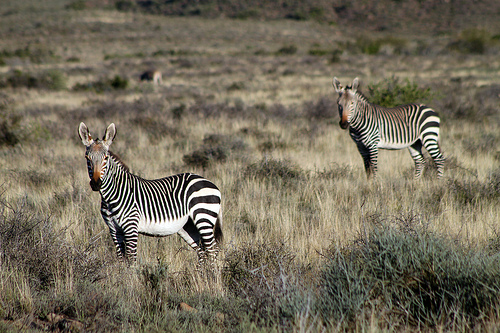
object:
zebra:
[79, 121, 225, 271]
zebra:
[332, 76, 447, 180]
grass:
[0, 0, 500, 333]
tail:
[214, 204, 224, 249]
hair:
[214, 216, 225, 243]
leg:
[422, 131, 445, 180]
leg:
[192, 212, 220, 271]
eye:
[105, 156, 109, 159]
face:
[85, 144, 107, 191]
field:
[1, 2, 500, 333]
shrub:
[368, 76, 437, 108]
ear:
[333, 76, 344, 92]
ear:
[352, 77, 359, 91]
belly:
[137, 214, 188, 237]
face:
[336, 89, 356, 129]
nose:
[90, 182, 101, 191]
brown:
[340, 114, 348, 122]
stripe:
[79, 122, 224, 281]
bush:
[109, 74, 129, 89]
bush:
[330, 54, 341, 64]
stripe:
[332, 77, 447, 181]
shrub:
[284, 9, 312, 20]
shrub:
[440, 25, 490, 55]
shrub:
[64, 0, 86, 10]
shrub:
[139, 0, 163, 16]